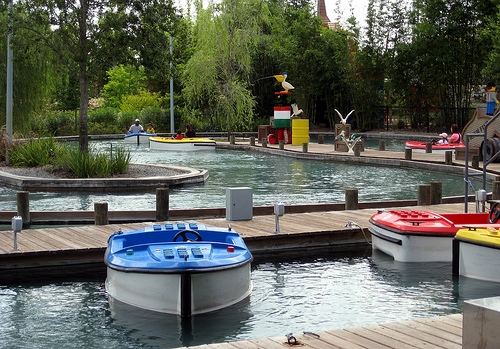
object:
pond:
[0, 133, 495, 232]